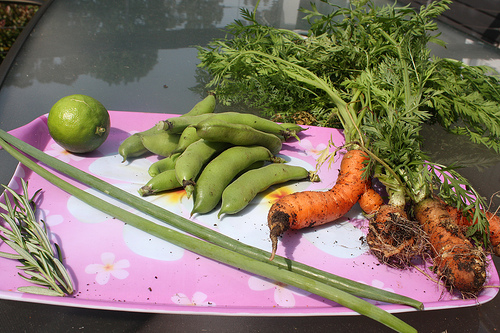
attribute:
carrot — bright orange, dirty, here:
[277, 141, 365, 240]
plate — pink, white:
[6, 107, 499, 325]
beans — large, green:
[130, 95, 312, 212]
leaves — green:
[222, 25, 365, 134]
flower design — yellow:
[78, 147, 373, 265]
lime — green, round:
[43, 94, 111, 154]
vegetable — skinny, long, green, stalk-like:
[6, 127, 424, 332]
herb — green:
[2, 176, 73, 298]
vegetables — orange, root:
[366, 148, 498, 299]